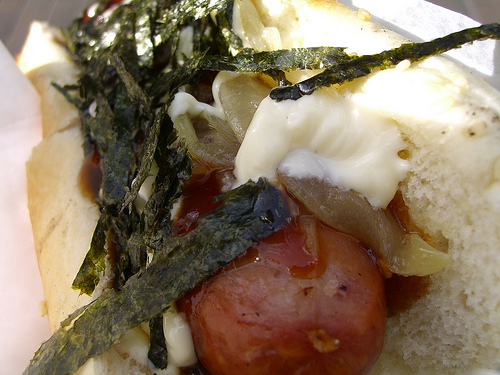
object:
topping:
[21, 0, 500, 374]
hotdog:
[188, 198, 388, 375]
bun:
[0, 0, 500, 375]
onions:
[170, 73, 449, 278]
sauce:
[262, 236, 316, 270]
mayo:
[233, 89, 409, 211]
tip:
[308, 326, 339, 358]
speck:
[340, 283, 348, 292]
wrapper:
[1, 0, 500, 375]